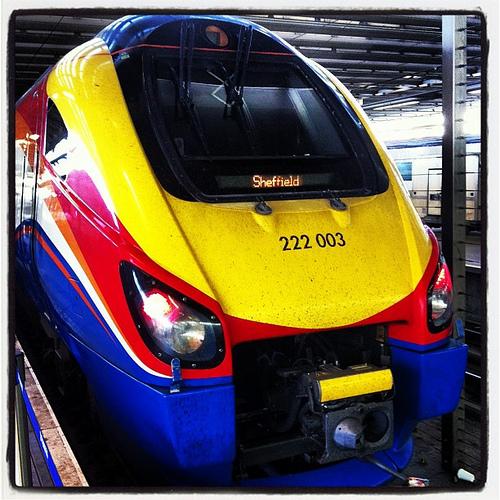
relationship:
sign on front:
[219, 172, 336, 187] [85, 12, 469, 485]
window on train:
[42, 93, 72, 185] [12, 14, 472, 484]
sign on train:
[219, 172, 336, 187] [12, 14, 472, 484]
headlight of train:
[118, 259, 224, 369] [12, 14, 472, 484]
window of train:
[113, 23, 390, 197] [12, 14, 472, 484]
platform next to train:
[11, 336, 89, 488] [12, 14, 472, 484]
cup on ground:
[456, 468, 475, 482] [14, 327, 486, 493]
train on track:
[12, 14, 472, 484] [11, 304, 483, 492]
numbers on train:
[276, 228, 350, 253] [12, 14, 472, 484]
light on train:
[112, 271, 297, 389] [84, 7, 389, 395]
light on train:
[415, 253, 469, 346] [12, 14, 472, 484]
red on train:
[79, 213, 116, 261] [12, 14, 472, 484]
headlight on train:
[118, 259, 224, 369] [12, 14, 472, 484]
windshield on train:
[113, 0, 392, 206] [12, 14, 472, 484]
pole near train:
[435, 16, 469, 330] [12, 14, 472, 484]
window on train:
[125, 51, 363, 186] [12, 14, 472, 484]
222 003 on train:
[270, 220, 356, 255] [12, 14, 472, 484]